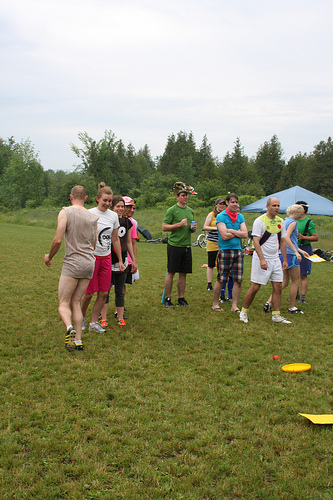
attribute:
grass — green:
[1, 216, 331, 500]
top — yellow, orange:
[205, 212, 219, 254]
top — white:
[86, 206, 122, 261]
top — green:
[163, 203, 199, 249]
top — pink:
[126, 217, 139, 251]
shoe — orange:
[115, 317, 129, 329]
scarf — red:
[223, 209, 241, 230]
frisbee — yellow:
[280, 360, 315, 378]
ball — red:
[269, 352, 279, 362]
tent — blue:
[239, 183, 333, 217]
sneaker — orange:
[98, 319, 109, 332]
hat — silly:
[171, 178, 197, 202]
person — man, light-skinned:
[158, 180, 199, 310]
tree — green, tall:
[156, 132, 218, 198]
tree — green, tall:
[68, 127, 133, 199]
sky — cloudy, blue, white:
[0, 2, 333, 174]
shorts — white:
[247, 247, 289, 288]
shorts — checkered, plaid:
[214, 246, 246, 286]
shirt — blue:
[217, 212, 249, 253]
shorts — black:
[165, 239, 195, 279]